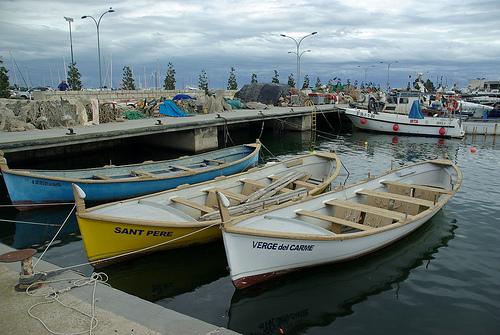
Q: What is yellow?
A: Boat.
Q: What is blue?
A: Sky.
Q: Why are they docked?
A: Not in use.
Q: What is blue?
A: Boat.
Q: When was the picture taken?
A: Daytime.